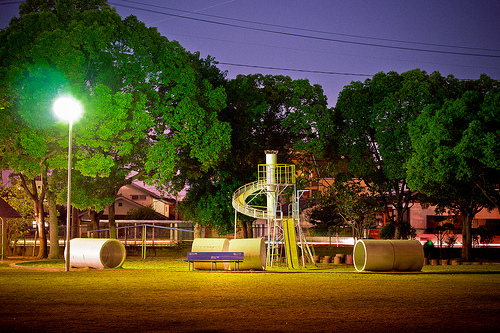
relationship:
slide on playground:
[229, 150, 326, 267] [34, 139, 446, 281]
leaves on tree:
[407, 94, 499, 212] [404, 76, 499, 258]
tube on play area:
[350, 236, 427, 279] [2, 212, 498, 332]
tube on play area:
[190, 233, 263, 270] [2, 212, 498, 332]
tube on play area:
[64, 233, 129, 271] [2, 212, 498, 332]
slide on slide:
[236, 163, 296, 270] [229, 150, 326, 267]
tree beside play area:
[404, 76, 499, 258] [2, 212, 498, 332]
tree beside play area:
[332, 66, 467, 240] [2, 212, 498, 332]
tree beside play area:
[183, 68, 338, 232] [2, 212, 498, 332]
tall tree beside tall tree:
[0, 1, 235, 263] [0, 1, 235, 263]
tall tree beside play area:
[0, 1, 235, 263] [2, 212, 498, 332]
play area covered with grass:
[2, 212, 498, 332] [3, 252, 494, 332]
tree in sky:
[404, 76, 499, 258] [0, 0, 499, 167]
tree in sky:
[332, 66, 467, 240] [0, 0, 499, 167]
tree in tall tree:
[183, 68, 338, 232] [0, 1, 235, 263]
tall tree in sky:
[0, 1, 235, 263] [0, 0, 499, 167]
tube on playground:
[64, 233, 129, 271] [38, 158, 471, 313]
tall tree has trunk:
[0, 1, 235, 263] [44, 168, 64, 258]